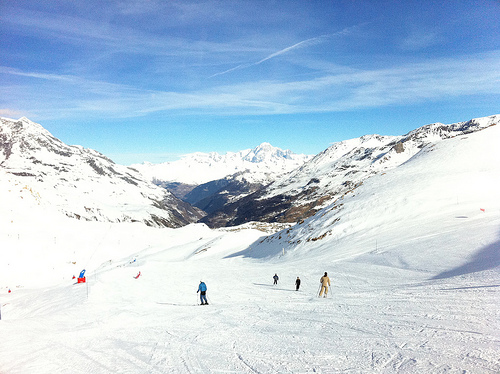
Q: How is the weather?
A: It is clear.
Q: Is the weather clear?
A: Yes, it is clear.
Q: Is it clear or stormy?
A: It is clear.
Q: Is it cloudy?
A: No, it is clear.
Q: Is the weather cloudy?
A: No, it is clear.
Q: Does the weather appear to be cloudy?
A: No, it is clear.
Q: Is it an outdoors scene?
A: Yes, it is outdoors.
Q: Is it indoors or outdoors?
A: It is outdoors.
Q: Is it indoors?
A: No, it is outdoors.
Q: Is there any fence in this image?
A: No, there are no fences.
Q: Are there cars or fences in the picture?
A: No, there are no fences or cars.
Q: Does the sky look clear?
A: Yes, the sky is clear.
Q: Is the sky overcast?
A: No, the sky is clear.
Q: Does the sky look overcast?
A: No, the sky is clear.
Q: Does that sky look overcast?
A: No, the sky is clear.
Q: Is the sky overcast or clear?
A: The sky is clear.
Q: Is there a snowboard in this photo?
A: No, there are no snowboards.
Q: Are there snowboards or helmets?
A: No, there are no snowboards or helmets.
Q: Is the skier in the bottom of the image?
A: Yes, the skier is in the bottom of the image.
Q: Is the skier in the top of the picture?
A: No, the skier is in the bottom of the image.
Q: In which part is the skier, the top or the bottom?
A: The skier is in the bottom of the image.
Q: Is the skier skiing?
A: Yes, the skier is skiing.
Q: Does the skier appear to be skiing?
A: Yes, the skier is skiing.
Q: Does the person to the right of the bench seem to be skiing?
A: Yes, the skier is skiing.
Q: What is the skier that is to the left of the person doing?
A: The skier is skiing.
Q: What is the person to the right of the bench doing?
A: The skier is skiing.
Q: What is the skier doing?
A: The skier is skiing.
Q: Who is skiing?
A: The skier is skiing.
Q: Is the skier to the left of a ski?
A: No, the skier is to the left of a person.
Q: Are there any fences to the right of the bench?
A: No, there is a skier to the right of the bench.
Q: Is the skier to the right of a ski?
A: No, the skier is to the right of the bench.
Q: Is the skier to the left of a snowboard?
A: No, the skier is to the left of a person.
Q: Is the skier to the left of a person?
A: Yes, the skier is to the left of a person.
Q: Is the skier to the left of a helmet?
A: No, the skier is to the left of a person.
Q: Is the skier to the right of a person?
A: No, the skier is to the left of a person.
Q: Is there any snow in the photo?
A: Yes, there is snow.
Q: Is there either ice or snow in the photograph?
A: Yes, there is snow.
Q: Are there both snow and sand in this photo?
A: No, there is snow but no sand.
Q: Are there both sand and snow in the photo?
A: No, there is snow but no sand.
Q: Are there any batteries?
A: No, there are no batteries.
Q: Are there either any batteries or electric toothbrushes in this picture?
A: No, there are no batteries or electric toothbrushes.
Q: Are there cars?
A: No, there are no cars.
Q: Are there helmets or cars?
A: No, there are no cars or helmets.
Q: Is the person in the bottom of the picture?
A: Yes, the person is in the bottom of the image.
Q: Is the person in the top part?
A: No, the person is in the bottom of the image.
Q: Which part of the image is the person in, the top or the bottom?
A: The person is in the bottom of the image.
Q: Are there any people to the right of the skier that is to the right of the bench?
A: Yes, there is a person to the right of the skier.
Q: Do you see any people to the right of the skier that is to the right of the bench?
A: Yes, there is a person to the right of the skier.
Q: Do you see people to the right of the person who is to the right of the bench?
A: Yes, there is a person to the right of the skier.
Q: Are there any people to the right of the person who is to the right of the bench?
A: Yes, there is a person to the right of the skier.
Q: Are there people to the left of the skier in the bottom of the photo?
A: No, the person is to the right of the skier.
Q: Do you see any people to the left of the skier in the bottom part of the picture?
A: No, the person is to the right of the skier.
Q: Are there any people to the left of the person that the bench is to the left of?
A: No, the person is to the right of the skier.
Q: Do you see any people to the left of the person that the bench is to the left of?
A: No, the person is to the right of the skier.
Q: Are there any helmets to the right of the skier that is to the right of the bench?
A: No, there is a person to the right of the skier.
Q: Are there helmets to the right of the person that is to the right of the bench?
A: No, there is a person to the right of the skier.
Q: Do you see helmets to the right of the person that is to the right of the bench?
A: No, there is a person to the right of the skier.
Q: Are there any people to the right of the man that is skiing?
A: Yes, there is a person to the right of the man.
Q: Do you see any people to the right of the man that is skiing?
A: Yes, there is a person to the right of the man.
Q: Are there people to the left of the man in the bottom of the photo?
A: No, the person is to the right of the man.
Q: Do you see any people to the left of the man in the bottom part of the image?
A: No, the person is to the right of the man.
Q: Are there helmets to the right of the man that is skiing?
A: No, there is a person to the right of the man.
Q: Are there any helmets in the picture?
A: No, there are no helmets.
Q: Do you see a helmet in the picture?
A: No, there are no helmets.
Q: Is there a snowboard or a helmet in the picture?
A: No, there are no helmets or snowboards.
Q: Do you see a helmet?
A: No, there are no helmets.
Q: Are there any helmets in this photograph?
A: No, there are no helmets.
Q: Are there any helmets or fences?
A: No, there are no helmets or fences.